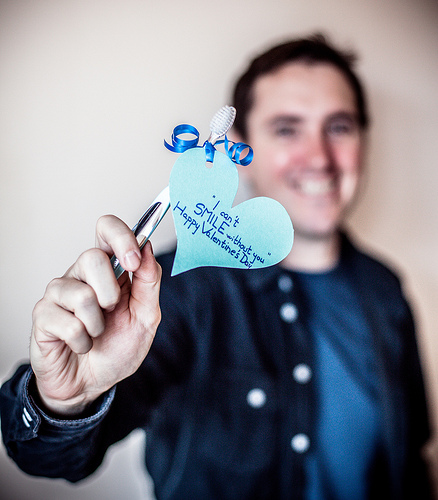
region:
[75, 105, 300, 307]
plastic toothbrush with note tied to it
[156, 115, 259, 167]
blue curled ribbon tied around toothbrush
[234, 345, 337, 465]
white buttons on denim shirt with pockets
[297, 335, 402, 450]
light blue shirt under denim shirt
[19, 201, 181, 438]
hand holding the plastic toothbrush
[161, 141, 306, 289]
heart shaped paper with handwritten note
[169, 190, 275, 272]
dark blue handwriting on light blue paper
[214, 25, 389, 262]
smiling face of man with dark hair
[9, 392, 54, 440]
buttons on the cuff of the denim shirt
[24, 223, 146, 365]
fingers with clean fingernails on them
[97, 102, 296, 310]
The toothbrush is brand new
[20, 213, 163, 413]
The hand of the man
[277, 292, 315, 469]
The buttons on the shirt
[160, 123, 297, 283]
The tag on the toothbrush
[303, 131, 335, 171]
The nose of the man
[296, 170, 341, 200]
The mouth of the man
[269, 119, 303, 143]
The eye of the man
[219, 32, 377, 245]
The head of the man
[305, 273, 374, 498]
The man has on a blue shirt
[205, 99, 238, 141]
The head of the toothbrush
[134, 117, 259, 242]
toothbrush with blue ribbon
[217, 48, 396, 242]
man smiling with toothbrush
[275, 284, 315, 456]
buttons on a jean shirt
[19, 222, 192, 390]
hand holding a clear toothbrush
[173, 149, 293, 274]
a note on a toothbrush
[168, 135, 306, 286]
heart shaped paper with writing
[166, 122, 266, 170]
blue ribbon holding a note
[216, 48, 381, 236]
man with dark colored hair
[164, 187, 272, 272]
blue print on paper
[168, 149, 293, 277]
a blue paper heart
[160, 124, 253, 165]
curled blue ribbon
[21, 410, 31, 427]
white buttons on the shirt cuff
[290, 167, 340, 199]
smile is showing the man's teeth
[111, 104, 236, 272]
a new toothbrush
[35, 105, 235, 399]
the man is holding a toothbrush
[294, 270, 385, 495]
light blue tee shirt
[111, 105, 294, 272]
toothbrush with a paper heart attached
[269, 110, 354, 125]
brown eye brows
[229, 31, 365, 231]
the man has brown hair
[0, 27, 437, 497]
A man in the foreground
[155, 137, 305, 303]
An outline of a heart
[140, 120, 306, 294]
The heart is wrapped around a ribbon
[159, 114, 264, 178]
The ribbon is blue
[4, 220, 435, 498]
Man is wearing a light jacket